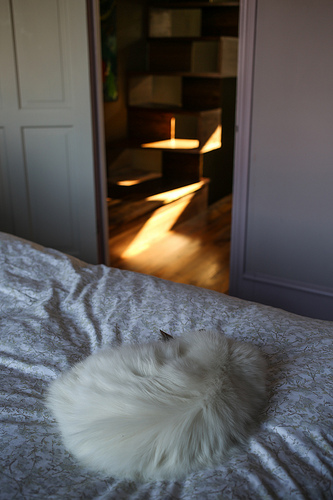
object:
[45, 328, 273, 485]
cat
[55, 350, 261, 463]
fur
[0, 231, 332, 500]
bed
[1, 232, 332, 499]
sheet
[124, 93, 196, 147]
boxes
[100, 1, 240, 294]
room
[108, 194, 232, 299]
floor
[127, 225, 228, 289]
sunlight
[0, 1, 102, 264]
door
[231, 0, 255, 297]
door jamb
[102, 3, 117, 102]
poster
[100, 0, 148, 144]
wall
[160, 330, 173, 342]
ear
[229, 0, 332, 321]
wall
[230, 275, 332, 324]
trim